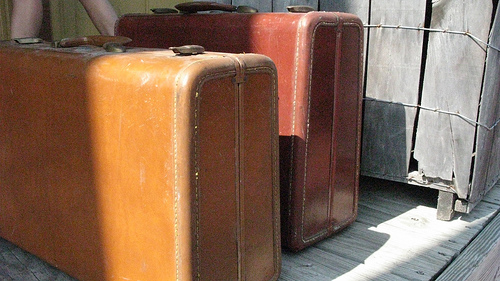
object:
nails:
[410, 235, 461, 275]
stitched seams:
[173, 8, 500, 281]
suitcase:
[0, 8, 365, 277]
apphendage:
[15, 1, 317, 54]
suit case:
[115, 2, 367, 253]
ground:
[381, 200, 457, 281]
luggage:
[0, 0, 365, 281]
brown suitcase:
[1, 35, 281, 279]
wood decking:
[337, 220, 435, 278]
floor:
[0, 178, 498, 279]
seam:
[234, 55, 248, 281]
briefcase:
[0, 34, 285, 277]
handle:
[49, 35, 132, 52]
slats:
[270, 186, 495, 281]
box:
[0, 2, 367, 237]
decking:
[280, 181, 498, 278]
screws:
[438, 252, 445, 256]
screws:
[411, 218, 419, 222]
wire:
[347, 24, 498, 130]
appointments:
[185, 87, 207, 191]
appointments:
[296, 108, 316, 140]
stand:
[226, 146, 498, 281]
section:
[386, 209, 413, 227]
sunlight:
[337, 205, 476, 281]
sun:
[88, 48, 188, 281]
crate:
[222, 0, 497, 222]